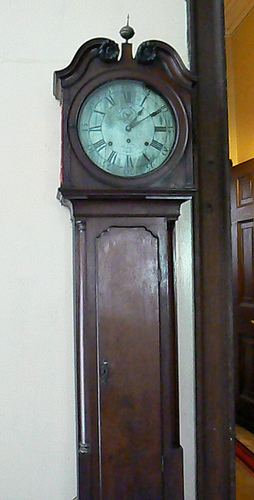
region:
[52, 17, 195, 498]
a brown grandfather clock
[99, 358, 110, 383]
a missing door handle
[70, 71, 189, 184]
an old clock face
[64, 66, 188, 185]
a clock face with roman numerals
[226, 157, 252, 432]
a brown opened door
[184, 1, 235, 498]
brown wooden wall trim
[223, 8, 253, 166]
a yellow painted wall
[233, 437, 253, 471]
a red and black piece of carpet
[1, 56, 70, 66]
a yellow stain on the wall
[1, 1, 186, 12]
a white painted wall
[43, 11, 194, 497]
a grandfather's clock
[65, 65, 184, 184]
the opening to the clock face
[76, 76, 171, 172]
the clock face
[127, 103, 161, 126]
the hands on the clock face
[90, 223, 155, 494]
door on the body of the clock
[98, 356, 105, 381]
the handle on the door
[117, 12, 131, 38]
round decoration on top of the clock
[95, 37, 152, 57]
wood rosettes on the clock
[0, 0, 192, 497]
white wall the clock is against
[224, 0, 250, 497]
another room to the right of the clock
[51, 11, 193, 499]
brown rectangular grandfather clock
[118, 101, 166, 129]
Clock hands pointing to 1:10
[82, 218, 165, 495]
long drawer door with black handle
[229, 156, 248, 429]
brown door with bevels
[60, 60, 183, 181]
an old light teal-colored clock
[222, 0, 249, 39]
thick trimming on ceiling border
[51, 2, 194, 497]
long old grandfather clock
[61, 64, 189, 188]
clock face with roman numerals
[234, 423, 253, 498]
red and yellow floor pattern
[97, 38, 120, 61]
black flower-shaped decoration